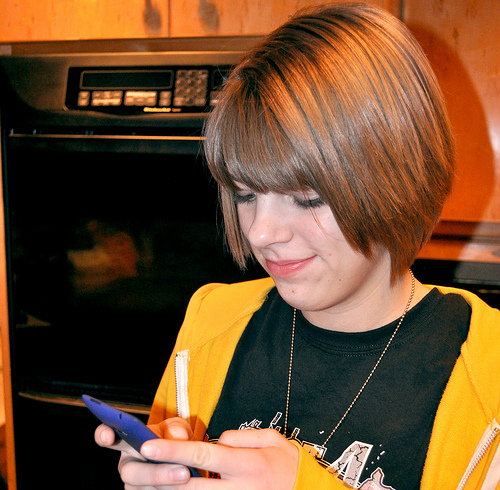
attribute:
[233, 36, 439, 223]
hair — straight, brown, short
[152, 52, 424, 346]
girl — texting, smiling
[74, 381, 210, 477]
phone — purple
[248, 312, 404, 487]
tshirt — black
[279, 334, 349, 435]
chain — silver